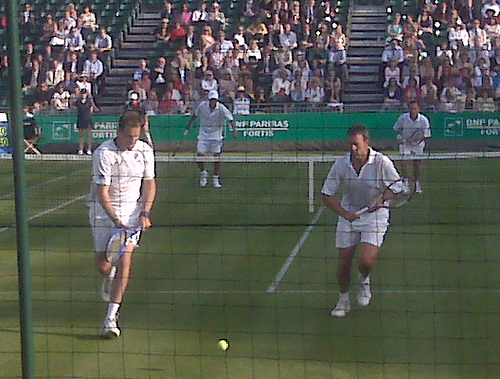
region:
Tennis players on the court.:
[76, 91, 433, 306]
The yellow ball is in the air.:
[183, 323, 235, 363]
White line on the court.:
[225, 193, 309, 305]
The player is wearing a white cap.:
[205, 92, 229, 107]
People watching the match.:
[151, 20, 406, 92]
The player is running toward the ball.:
[203, 123, 408, 355]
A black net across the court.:
[155, 141, 461, 217]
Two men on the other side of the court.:
[181, 88, 427, 191]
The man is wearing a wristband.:
[133, 206, 155, 221]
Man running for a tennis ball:
[83, 108, 160, 343]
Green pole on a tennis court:
[1, 1, 45, 377]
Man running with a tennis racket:
[316, 121, 421, 325]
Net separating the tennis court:
[0, 145, 499, 228]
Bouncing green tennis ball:
[194, 324, 248, 370]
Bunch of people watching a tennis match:
[0, 0, 499, 117]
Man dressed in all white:
[178, 86, 235, 196]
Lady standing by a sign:
[71, 87, 100, 160]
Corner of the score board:
[0, 119, 18, 161]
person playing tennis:
[310, 119, 422, 326]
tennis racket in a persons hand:
[349, 173, 421, 227]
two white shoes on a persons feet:
[325, 269, 381, 325]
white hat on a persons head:
[207, 89, 222, 104]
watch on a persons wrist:
[137, 208, 154, 220]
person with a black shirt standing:
[72, 87, 99, 159]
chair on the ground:
[21, 115, 42, 160]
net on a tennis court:
[2, 147, 498, 233]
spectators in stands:
[0, 2, 117, 117]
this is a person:
[321, 125, 407, 325]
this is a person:
[53, 105, 180, 350]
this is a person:
[179, 96, 251, 199]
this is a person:
[376, 95, 450, 201]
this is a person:
[297, 65, 331, 114]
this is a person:
[376, 56, 395, 96]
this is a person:
[401, 75, 427, 117]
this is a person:
[439, 81, 469, 126]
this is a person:
[59, 81, 99, 148]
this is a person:
[206, 50, 241, 81]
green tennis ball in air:
[210, 333, 242, 353]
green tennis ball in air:
[201, 330, 247, 360]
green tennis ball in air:
[210, 328, 247, 359]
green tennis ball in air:
[208, 333, 238, 358]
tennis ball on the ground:
[218, 338, 226, 350]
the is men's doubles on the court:
[86, 90, 460, 341]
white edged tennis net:
[23, 148, 499, 225]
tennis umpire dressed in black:
[73, 86, 96, 158]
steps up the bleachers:
[341, 3, 394, 110]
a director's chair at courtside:
[14, 116, 43, 157]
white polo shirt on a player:
[316, 144, 401, 214]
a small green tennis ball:
[214, 335, 236, 351]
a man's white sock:
[108, 302, 122, 319]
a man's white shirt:
[322, 150, 408, 212]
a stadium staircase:
[342, 1, 389, 107]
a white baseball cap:
[205, 88, 220, 100]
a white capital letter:
[280, 118, 290, 128]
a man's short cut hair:
[117, 110, 149, 134]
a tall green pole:
[3, 0, 44, 377]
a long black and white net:
[3, 145, 497, 201]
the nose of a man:
[347, 141, 359, 151]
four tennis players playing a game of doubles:
[89, 86, 436, 337]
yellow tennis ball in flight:
[212, 332, 235, 355]